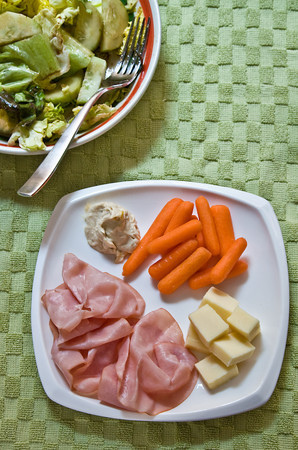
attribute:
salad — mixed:
[2, 1, 146, 151]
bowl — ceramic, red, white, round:
[1, 0, 162, 158]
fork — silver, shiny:
[16, 16, 152, 198]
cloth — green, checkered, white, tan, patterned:
[0, 0, 297, 449]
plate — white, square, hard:
[32, 178, 291, 423]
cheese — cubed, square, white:
[183, 286, 262, 390]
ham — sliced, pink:
[41, 252, 198, 416]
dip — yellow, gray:
[82, 202, 141, 264]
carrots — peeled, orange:
[121, 195, 249, 297]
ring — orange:
[0, 1, 155, 150]